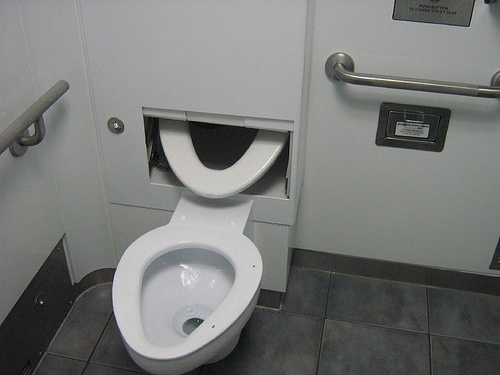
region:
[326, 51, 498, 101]
shiny metal grab bar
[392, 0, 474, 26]
bottom of square sign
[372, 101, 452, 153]
square door with label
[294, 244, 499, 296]
molding on bottom of wall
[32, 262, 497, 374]
square bathroom floor tiles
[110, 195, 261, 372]
toilet with seat attached to wall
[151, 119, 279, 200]
edge of toilet seat in wall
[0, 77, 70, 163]
wood bar attached to wall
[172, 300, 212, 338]
water in toilet bowl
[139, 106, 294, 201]
square opening in wall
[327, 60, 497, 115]
A handle on a wall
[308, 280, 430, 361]
a gray tile floor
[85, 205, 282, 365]
a white toilet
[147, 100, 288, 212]
a seat to a toilet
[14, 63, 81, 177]
a handle rail on a wall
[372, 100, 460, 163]
a silver door on a wall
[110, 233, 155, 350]
a toilet bowl rim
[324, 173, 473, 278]
A white wall in a bathroom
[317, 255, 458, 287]
a gray base board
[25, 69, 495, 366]
a bathroom with a gray tile floor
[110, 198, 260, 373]
a white toilet bowl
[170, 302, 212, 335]
water in the toilet bowl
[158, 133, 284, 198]
a toilet seat in the wall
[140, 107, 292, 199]
an adjustable toilet seat in the wall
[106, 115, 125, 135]
the toilet's flush button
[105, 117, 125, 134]
flush button to the toilet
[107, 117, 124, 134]
the toilet's flush button on the wall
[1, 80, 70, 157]
a metal handlebar affixed to the bathroom wall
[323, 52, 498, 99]
a silver metal handlebar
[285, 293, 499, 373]
ceramic on the bathroom's floor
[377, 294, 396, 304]
edge of a floor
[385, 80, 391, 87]
part of a rail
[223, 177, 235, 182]
edge of a toilet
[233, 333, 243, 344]
bottom of a toilet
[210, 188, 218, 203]
part of a seat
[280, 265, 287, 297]
corner of a toilet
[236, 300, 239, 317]
part of the toilet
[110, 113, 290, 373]
a toilet in the wall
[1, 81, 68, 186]
metal railing in a bathroom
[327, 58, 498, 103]
metal railing in a bathroom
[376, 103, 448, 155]
a metal wase dispenser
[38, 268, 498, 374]
a grey tiled floor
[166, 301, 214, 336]
water in a toilet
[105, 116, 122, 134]
button to flush toilet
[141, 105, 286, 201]
seat reteacting into the wall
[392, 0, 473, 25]
a silver and black sign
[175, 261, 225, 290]
light reflected off a toilet